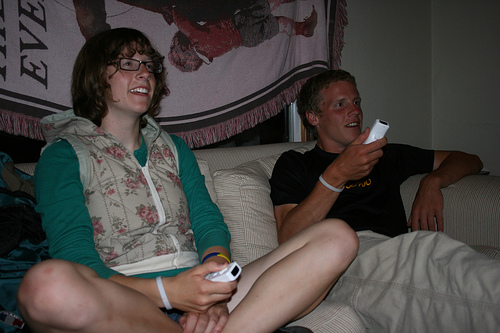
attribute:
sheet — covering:
[331, 231, 492, 331]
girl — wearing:
[14, 26, 360, 331]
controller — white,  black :
[194, 260, 244, 283]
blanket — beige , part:
[350, 225, 499, 331]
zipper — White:
[138, 165, 167, 227]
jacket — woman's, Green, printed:
[36, 104, 229, 269]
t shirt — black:
[265, 140, 440, 243]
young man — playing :
[266, 69, 486, 237]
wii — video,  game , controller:
[364, 113, 391, 145]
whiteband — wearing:
[318, 168, 347, 201]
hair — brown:
[295, 67, 357, 135]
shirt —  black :
[267, 142, 434, 237]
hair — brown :
[52, 22, 145, 123]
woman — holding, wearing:
[24, 21, 356, 328]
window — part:
[227, 103, 298, 143]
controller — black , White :
[360, 117, 397, 157]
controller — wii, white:
[360, 118, 395, 151]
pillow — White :
[218, 163, 274, 254]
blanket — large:
[3, 2, 328, 40]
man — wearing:
[265, 65, 491, 256]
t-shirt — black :
[272, 136, 437, 241]